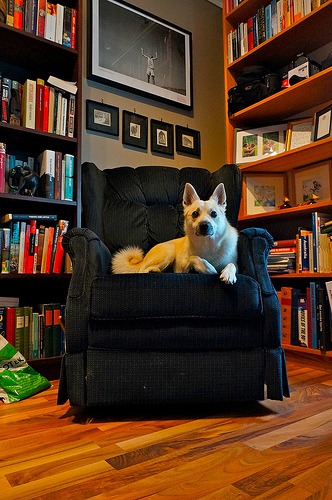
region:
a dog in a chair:
[85, 160, 269, 301]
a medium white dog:
[92, 186, 248, 309]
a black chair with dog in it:
[59, 156, 311, 440]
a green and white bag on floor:
[0, 343, 64, 405]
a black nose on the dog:
[198, 221, 212, 238]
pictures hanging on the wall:
[82, 0, 228, 164]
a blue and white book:
[64, 147, 78, 206]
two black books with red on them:
[40, 299, 63, 367]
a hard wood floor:
[6, 362, 328, 499]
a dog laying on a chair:
[67, 138, 313, 318]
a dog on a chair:
[49, 174, 298, 370]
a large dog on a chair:
[135, 129, 265, 332]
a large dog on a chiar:
[97, 196, 232, 380]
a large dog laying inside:
[100, 178, 318, 378]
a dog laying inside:
[128, 160, 316, 393]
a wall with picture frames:
[78, 67, 322, 241]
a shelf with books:
[12, 207, 100, 400]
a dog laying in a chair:
[99, 168, 256, 287]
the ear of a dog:
[178, 179, 199, 207]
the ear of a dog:
[210, 179, 228, 207]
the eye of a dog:
[188, 207, 202, 220]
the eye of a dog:
[208, 207, 221, 220]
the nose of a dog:
[197, 219, 213, 231]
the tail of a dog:
[110, 243, 143, 275]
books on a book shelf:
[0, 208, 68, 279]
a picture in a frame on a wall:
[87, 0, 196, 113]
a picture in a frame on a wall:
[83, 95, 120, 137]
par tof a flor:
[198, 421, 218, 440]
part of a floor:
[176, 456, 197, 474]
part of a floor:
[221, 419, 238, 437]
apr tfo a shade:
[243, 390, 266, 446]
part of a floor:
[217, 437, 235, 464]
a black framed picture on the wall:
[84, 0, 194, 112]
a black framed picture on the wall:
[85, 98, 119, 137]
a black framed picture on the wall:
[122, 109, 149, 148]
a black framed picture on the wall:
[149, 118, 174, 155]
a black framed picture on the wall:
[174, 124, 200, 156]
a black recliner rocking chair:
[56, 161, 289, 407]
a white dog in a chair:
[111, 177, 238, 285]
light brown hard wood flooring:
[1, 346, 330, 498]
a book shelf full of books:
[2, 0, 82, 379]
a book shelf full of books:
[221, 0, 331, 355]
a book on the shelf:
[295, 225, 322, 275]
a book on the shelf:
[271, 254, 283, 274]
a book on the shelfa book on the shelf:
[293, 236, 311, 268]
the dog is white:
[111, 182, 241, 284]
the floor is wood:
[0, 355, 331, 498]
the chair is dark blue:
[57, 161, 288, 417]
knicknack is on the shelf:
[276, 195, 292, 211]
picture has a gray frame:
[84, 97, 119, 137]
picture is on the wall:
[121, 108, 148, 148]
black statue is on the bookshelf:
[6, 165, 40, 196]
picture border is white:
[86, 1, 194, 111]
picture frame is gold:
[285, 116, 318, 149]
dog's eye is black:
[191, 210, 199, 218]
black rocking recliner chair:
[52, 158, 294, 425]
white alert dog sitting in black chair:
[110, 178, 239, 283]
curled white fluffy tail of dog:
[110, 230, 150, 280]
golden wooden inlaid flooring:
[2, 346, 329, 498]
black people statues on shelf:
[7, 164, 38, 194]